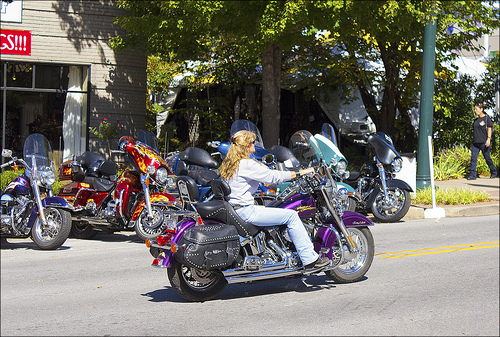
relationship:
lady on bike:
[224, 128, 337, 271] [160, 133, 379, 297]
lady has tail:
[224, 131, 254, 175] [210, 145, 231, 172]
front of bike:
[307, 145, 365, 201] [297, 208, 402, 291]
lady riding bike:
[224, 128, 337, 271] [160, 133, 379, 297]